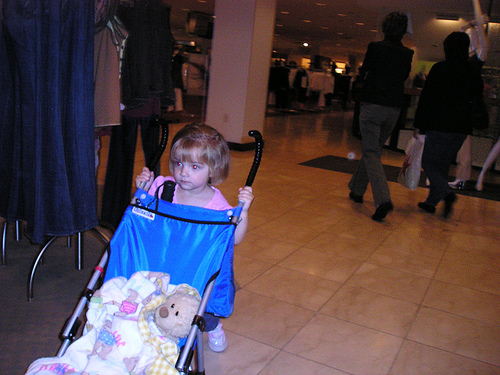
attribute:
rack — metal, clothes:
[1, 0, 114, 301]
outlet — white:
[222, 112, 229, 122]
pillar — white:
[205, 2, 277, 149]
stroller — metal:
[47, 117, 273, 369]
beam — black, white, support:
[197, 2, 279, 151]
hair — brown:
[163, 116, 249, 191]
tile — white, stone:
[317, 283, 420, 337]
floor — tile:
[2, 107, 499, 372]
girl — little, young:
[131, 125, 255, 353]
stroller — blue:
[42, 104, 306, 373]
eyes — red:
[173, 160, 200, 172]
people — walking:
[341, 30, 486, 182]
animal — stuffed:
[103, 255, 185, 351]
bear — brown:
[151, 265, 211, 352]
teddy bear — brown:
[153, 292, 199, 339]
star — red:
[402, 154, 415, 175]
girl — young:
[121, 114, 266, 355]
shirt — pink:
[145, 180, 232, 220]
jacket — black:
[346, 41, 412, 105]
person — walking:
[350, 5, 410, 220]